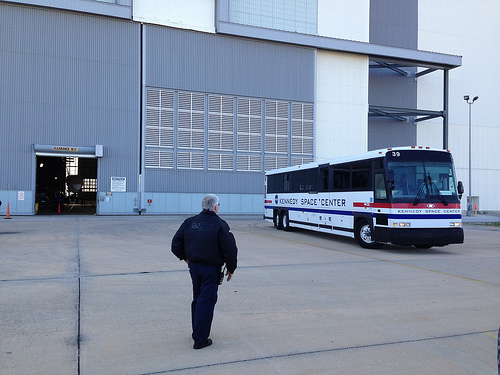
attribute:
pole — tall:
[462, 94, 477, 210]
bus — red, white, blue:
[371, 144, 469, 257]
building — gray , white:
[6, 3, 498, 290]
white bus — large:
[241, 141, 474, 252]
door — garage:
[25, 140, 135, 210]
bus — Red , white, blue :
[258, 147, 498, 247]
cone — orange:
[0, 200, 17, 225]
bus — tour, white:
[262, 141, 467, 255]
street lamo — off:
[460, 91, 486, 220]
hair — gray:
[201, 193, 220, 212]